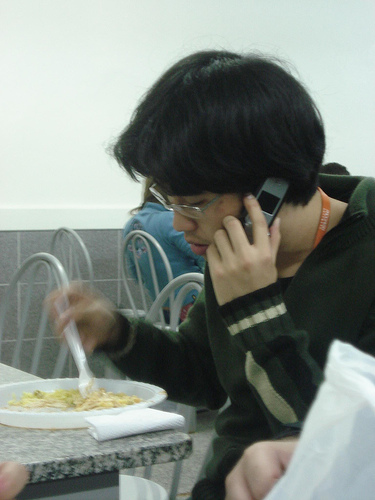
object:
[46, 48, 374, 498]
man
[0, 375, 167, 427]
bowl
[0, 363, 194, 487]
table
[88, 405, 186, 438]
napkin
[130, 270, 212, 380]
chairs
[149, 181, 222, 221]
glasses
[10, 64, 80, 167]
blue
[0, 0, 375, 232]
wall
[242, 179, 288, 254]
phone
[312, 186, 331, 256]
lanyard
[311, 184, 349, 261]
neck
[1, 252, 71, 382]
chair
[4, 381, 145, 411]
food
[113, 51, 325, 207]
hair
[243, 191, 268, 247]
finger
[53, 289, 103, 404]
fork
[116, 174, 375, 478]
shirt